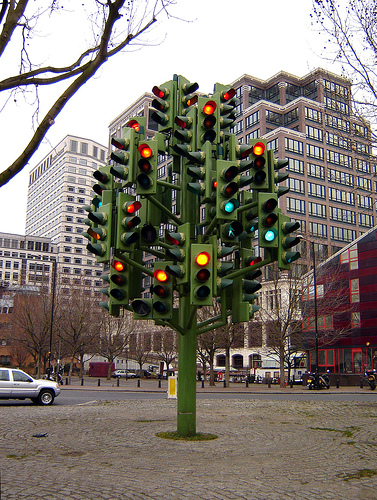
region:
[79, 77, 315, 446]
multiple street lights on one post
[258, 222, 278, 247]
the light is green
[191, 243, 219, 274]
the light is red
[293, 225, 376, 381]
the building is red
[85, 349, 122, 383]
the car is red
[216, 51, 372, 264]
the building is brown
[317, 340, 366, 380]
door and window frames are red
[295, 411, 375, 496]
patches of grass on the ground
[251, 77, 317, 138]
the building windows are black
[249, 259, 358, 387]
tree in front of building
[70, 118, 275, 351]
tree made of lights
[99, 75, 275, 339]
red and green traffic lights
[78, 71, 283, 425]
lights on green pole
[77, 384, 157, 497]
grey sidewalk around pole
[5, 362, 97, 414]
grey van on road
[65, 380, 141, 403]
road is dark grey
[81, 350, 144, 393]
wood posts on sidewalk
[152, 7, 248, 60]
sky is grey and cloudy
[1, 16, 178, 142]
bare tree near decorative tree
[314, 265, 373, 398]
red building on right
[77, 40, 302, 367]
many traffic lights on one pole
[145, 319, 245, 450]
the pole is green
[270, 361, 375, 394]
the motorcycles are parked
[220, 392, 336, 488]
the ground is grey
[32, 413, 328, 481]
the ground is made of bricks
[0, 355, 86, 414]
the car is grey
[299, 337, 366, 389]
the window frames are bright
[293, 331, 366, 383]
the window frames are red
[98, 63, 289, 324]
most of the lights are red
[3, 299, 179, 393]
the trees are bare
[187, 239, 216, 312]
traffic light on a pole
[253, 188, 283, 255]
traffic light on a pole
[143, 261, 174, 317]
traffic light on a pole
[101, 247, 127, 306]
traffic light on a pole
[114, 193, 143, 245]
traffic light on a pole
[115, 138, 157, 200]
traffic light on pole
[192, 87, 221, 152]
traffic light on a pole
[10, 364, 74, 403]
car on a street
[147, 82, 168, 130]
traffic light on a pole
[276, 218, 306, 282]
traffic light on a pole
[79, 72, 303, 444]
Green pole with several traffic lights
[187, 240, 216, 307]
Traffic light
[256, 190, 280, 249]
Traffic light on green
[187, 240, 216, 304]
Traffic light on yellow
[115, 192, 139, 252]
Traffic light on red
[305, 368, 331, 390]
Couple of parked motorcycles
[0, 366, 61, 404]
Silver van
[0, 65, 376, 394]
Group of buildings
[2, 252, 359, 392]
Several tree branches with no leaves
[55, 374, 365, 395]
Row of small poles in the parking lot